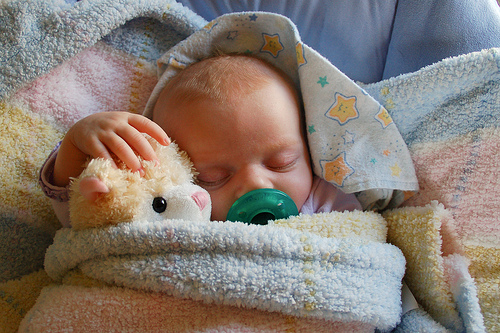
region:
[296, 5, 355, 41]
this is a pillow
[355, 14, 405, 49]
the pillow is blue in color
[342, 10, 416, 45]
the pillow is big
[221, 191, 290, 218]
this is a sucker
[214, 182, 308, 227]
the sucker is in the mouth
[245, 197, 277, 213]
the sucker is green in color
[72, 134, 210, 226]
this is a teddy bear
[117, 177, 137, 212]
the teddy is small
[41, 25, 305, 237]
this is a baby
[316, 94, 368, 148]
the sheet is blue in color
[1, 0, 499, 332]
A sleeping infant.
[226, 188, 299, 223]
Green pacifier in the infant's mouth.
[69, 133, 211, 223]
A fluffy toy bear next to the infant.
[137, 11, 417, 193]
Blue receiving blanket.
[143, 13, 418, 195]
Yellow and blue stars on the blanket.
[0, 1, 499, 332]
Fluffy striped blanket under the baby.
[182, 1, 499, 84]
Blue cushioned crib bumper pad.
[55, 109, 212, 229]
Baby's hand on the toy bear's head.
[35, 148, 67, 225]
Sleeve of an infant garment.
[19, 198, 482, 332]
A baby and a bear wrapped in a fluffy blanket.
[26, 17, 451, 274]
a sleeping baby with a teddy bear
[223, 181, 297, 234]
a green pacifier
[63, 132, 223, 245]
a yellow stuffed bear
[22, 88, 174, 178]
a baby's hand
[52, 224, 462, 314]
a baby blanket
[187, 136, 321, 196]
the eyes of a sleeping baby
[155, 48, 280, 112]
the hair of a newborn baby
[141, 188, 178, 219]
the eye of a stuffed animal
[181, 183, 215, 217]
the nose of a stuffed animal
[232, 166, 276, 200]
the nose of a newborn baby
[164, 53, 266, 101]
hair of the baby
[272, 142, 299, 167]
eye of the baby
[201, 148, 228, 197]
eye of the baby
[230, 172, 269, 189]
nose of the baby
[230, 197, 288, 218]
pacifier in baby's mouth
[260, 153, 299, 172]
the eye is closed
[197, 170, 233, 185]
the eye is closed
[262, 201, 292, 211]
the pacifier is green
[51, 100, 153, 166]
hand of the baby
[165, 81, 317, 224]
the baby is sleeping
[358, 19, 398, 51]
this is a pillow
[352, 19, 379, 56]
the pillow is big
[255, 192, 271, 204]
the sucker is green in color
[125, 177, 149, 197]
the teddy is brown in color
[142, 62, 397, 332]
this is a baby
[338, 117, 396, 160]
the cloth is blue in color